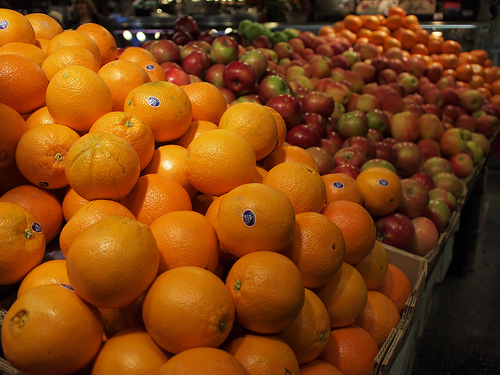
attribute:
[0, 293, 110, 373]
corner — bottom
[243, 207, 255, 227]
sticker — blue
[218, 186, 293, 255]
orange — large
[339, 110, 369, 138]
apple — green, red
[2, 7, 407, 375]
oranges — stacked, closest, piled, navels, numerous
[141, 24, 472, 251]
apples — stacked, piled, numerous, scattered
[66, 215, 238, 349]
three oranges — grouped together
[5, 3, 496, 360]
fruit — bunch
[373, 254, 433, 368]
box — brown, cardboard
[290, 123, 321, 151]
apple — red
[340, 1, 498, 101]
oranges — furthest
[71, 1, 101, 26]
woman — walking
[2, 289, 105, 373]
orange — large, closest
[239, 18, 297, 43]
five apples — green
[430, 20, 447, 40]
light — glaring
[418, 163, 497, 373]
concrete — dark